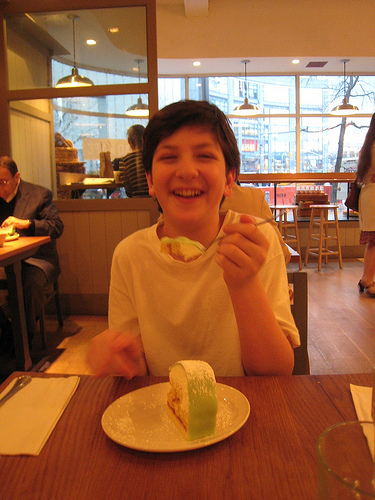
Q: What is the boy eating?
A: Cake.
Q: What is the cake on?
A: A plate.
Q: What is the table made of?
A: Wood.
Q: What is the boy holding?
A: A spoon.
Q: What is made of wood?
A: The table.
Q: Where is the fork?
A: In the boy's hand.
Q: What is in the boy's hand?
A: A fork.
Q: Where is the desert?
A: On the plate.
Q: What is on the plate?
A: The dessert.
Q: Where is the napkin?
A: On the table.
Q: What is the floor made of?
A: Wood.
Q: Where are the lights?
A: Hanging from the ceiling.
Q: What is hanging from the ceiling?
A: Lights.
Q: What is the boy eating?
A: Cake.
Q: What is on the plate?
A: Cake.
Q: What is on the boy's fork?
A: Cake.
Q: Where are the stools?
A: Near the window.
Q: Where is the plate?
A: On the table.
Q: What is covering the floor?
A: Wood planks.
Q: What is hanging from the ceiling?
A: Light fixtures.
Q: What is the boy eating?
A: Cake.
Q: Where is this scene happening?
A: Restaurant.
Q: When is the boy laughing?
A: Now.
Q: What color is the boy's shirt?
A: White.